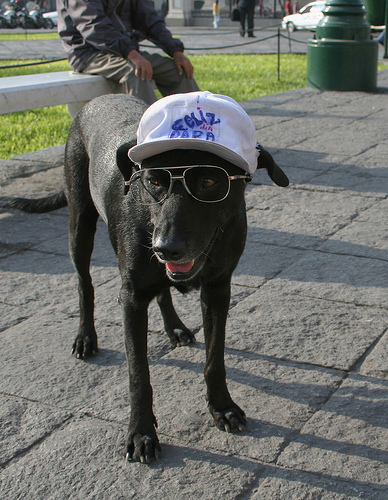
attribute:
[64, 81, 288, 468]
dog — black in color, labrador retriever, black, black colored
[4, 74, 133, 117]
bench — marble, white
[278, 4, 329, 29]
car — sedan, white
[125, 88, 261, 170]
cap — white, white in color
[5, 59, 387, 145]
grass — large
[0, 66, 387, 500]
sidewalk — concrete, stone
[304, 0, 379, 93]
streetlight — green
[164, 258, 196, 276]
tongue — pink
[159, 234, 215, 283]
mouth — open